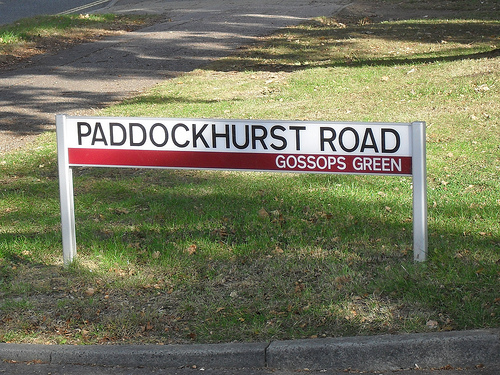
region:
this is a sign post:
[55, 117, 432, 275]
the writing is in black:
[317, 121, 401, 161]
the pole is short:
[404, 114, 431, 264]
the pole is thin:
[411, 125, 430, 259]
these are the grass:
[230, 225, 319, 274]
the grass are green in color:
[284, 182, 351, 231]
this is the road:
[144, 16, 191, 66]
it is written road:
[313, 124, 405, 156]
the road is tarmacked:
[181, 10, 245, 46]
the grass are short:
[310, 195, 370, 239]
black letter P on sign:
[71, 112, 91, 148]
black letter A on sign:
[90, 119, 109, 147]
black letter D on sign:
[123, 121, 147, 148]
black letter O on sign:
[147, 118, 169, 151]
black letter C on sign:
[167, 121, 191, 151]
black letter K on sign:
[187, 118, 208, 153]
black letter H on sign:
[207, 121, 233, 154]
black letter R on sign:
[247, 119, 268, 151]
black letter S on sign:
[265, 121, 290, 152]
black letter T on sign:
[288, 121, 307, 150]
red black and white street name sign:
[48, 108, 433, 275]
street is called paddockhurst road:
[48, 108, 430, 288]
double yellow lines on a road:
[47, 0, 115, 24]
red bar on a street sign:
[63, 143, 412, 180]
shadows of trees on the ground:
[6, 21, 496, 145]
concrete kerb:
[1, 324, 498, 372]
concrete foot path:
[0, 5, 334, 167]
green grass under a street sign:
[3, 127, 498, 328]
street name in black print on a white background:
[52, 109, 414, 161]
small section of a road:
[1, 2, 112, 32]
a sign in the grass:
[48, 110, 435, 270]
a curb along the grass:
[3, 324, 498, 373]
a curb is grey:
[0, 318, 497, 373]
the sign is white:
[51, 113, 436, 268]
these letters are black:
[61, 116, 404, 157]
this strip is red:
[59, 144, 412, 176]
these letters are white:
[267, 154, 407, 177]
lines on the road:
[51, 1, 116, 21]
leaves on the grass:
[28, 12, 498, 345]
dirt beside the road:
[246, 2, 393, 64]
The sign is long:
[40, 102, 433, 255]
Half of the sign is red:
[52, 147, 409, 166]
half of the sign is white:
[64, 109, 421, 149]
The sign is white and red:
[40, 103, 442, 217]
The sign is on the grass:
[20, 92, 467, 309]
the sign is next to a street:
[77, 63, 494, 373]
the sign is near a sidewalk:
[0, 39, 125, 180]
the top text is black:
[76, 109, 408, 146]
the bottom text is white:
[262, 152, 409, 176]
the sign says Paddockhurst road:
[62, 105, 412, 152]